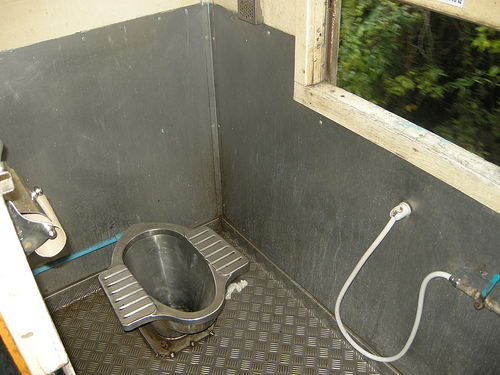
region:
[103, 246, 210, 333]
stainless steel open toilet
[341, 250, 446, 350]
white hose on wall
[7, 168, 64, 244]
stainless object holding towel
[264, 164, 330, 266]
wall is gray with white streaks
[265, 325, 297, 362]
floor is gray and patterned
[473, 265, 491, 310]
blue clamp holding hose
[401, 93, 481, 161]
green trees outside of window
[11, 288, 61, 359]
part of white wall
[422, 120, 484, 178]
white framed opening to window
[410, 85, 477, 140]
window has no glass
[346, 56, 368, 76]
Green leaves on the tree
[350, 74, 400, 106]
Green leaves on the tree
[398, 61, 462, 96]
Green leaves on the tree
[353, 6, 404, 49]
Green leaves on the tree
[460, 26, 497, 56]
Green leaves on the tree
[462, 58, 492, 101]
Green leaves on the tree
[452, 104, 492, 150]
Green leaves on the tree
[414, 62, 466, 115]
Green leaves on the tree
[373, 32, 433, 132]
Green leaves on the tree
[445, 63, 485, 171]
Green leaves on the tree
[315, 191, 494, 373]
white cord plugged into wall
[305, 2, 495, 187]
the window is open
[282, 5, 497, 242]
window frame is white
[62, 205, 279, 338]
the toilet is silver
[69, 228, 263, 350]
toilet attached to floor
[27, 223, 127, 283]
blue pipe attached to toilet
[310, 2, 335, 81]
paint chipping off frame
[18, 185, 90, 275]
the pipe is white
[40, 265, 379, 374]
floor made of metal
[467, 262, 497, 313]
blue piece on pipe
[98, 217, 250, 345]
gray metal toilet riveted to gray floor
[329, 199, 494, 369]
white cleansing hose with green on off handle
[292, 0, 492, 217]
window in a bathroom with worn white painted frame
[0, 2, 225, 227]
gray metalic wall piece attached behind the toilet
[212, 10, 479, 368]
gray metallic wall next to toilet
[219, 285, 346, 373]
textured metal flooring of bathroom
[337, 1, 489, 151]
green shrubbery outside bathroom window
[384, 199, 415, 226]
nozzle of white cleansing hose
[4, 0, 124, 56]
white wall above gray metal wall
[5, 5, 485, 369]
bathroom outside of the United States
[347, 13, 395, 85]
The leaves are short and green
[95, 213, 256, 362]
The toilet is stainless steel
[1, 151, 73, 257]
The toilet paper holder on the wall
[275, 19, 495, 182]
The window is open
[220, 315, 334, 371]
The floor is made of stainless steel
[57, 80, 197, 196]
The wall is made of stainless steel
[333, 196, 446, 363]
The pipe is the color white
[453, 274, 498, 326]
The pipe is the color gray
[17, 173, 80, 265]
The toilet paper is empty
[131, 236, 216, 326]
No water in the toilet